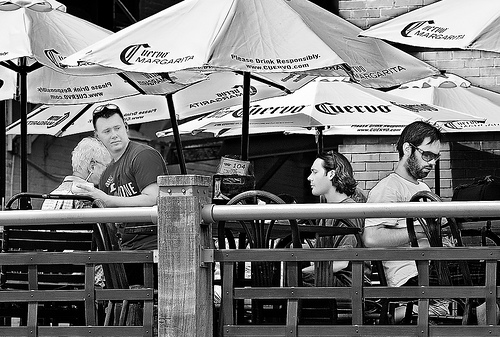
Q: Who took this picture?
A: A pedestrian.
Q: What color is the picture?
A: Black & White.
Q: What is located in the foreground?
A: A rail.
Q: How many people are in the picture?
A: 4.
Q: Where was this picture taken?
A: Restaurant.